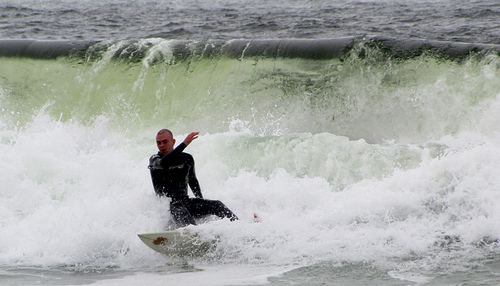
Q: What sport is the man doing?
A: Surfing.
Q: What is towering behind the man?
A: Wave.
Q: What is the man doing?
A: Surfing.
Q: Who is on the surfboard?
A: Man in black wet suit.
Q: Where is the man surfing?
A: In the ocean.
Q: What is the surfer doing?
A: Riding a wave.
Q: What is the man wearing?
A: A black wetsuit.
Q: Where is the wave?
A: Behind the man.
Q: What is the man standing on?
A: A surfboard.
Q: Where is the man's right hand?
A: In the air.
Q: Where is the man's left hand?
A: In the water.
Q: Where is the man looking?
A: At the water.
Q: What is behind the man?
A: Waves.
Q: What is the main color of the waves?
A: White.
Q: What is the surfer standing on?
A: Surfboard.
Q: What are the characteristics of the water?
A: White and foamy.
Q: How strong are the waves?
A: Very strong.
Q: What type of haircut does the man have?
A: Buzzcut.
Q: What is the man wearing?
A: Wetsuit.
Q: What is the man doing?
A: Surfing.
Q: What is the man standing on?
A: A surfboard.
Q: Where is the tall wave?
A: Behind the surfer.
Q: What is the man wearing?
A: A black wetsuit.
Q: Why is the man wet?
A: He is surfing.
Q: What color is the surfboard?
A: White.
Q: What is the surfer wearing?
A: A wet suit.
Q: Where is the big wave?
A: Directly behind the surfer.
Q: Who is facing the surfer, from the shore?
A: The photographer.